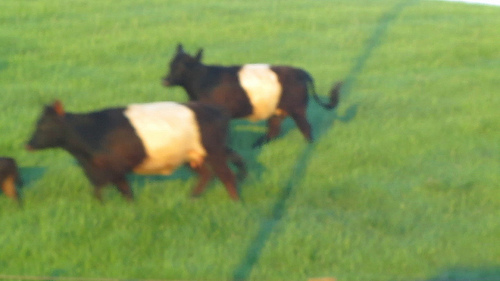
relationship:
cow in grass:
[26, 99, 248, 202] [366, 28, 482, 233]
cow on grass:
[26, 99, 248, 202] [251, 145, 491, 272]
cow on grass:
[156, 37, 344, 151] [251, 145, 491, 272]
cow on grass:
[26, 99, 248, 202] [4, 0, 497, 280]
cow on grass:
[156, 37, 344, 151] [4, 0, 497, 280]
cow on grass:
[163, 41, 344, 151] [4, 0, 497, 280]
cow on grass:
[4, 62, 458, 250] [4, 0, 497, 280]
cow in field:
[26, 99, 248, 202] [342, 16, 499, 268]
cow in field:
[26, 99, 248, 202] [2, 1, 498, 279]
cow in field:
[156, 37, 344, 151] [2, 1, 498, 279]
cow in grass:
[26, 99, 248, 202] [49, 202, 452, 272]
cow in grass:
[156, 37, 344, 151] [49, 202, 452, 272]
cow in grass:
[163, 41, 344, 151] [4, 0, 497, 280]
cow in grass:
[26, 99, 248, 202] [4, 0, 497, 280]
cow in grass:
[156, 37, 344, 151] [315, 144, 495, 264]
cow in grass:
[26, 99, 248, 202] [315, 144, 495, 264]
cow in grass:
[26, 99, 248, 202] [0, 0, 500, 281]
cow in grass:
[156, 37, 344, 151] [0, 0, 500, 281]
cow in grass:
[163, 41, 344, 151] [406, 105, 458, 159]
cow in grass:
[26, 99, 248, 202] [406, 105, 458, 159]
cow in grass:
[156, 37, 344, 151] [4, 0, 497, 280]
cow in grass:
[163, 41, 344, 151] [294, 160, 498, 280]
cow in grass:
[26, 99, 248, 202] [294, 160, 498, 280]